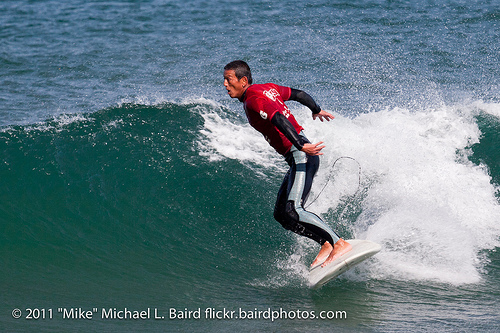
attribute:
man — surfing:
[220, 61, 351, 270]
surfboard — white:
[306, 238, 383, 291]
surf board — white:
[309, 237, 384, 286]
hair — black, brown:
[222, 60, 252, 86]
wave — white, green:
[3, 96, 499, 290]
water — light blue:
[2, 0, 499, 332]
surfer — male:
[222, 59, 353, 267]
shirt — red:
[239, 83, 305, 156]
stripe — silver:
[290, 145, 339, 245]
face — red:
[223, 69, 244, 100]